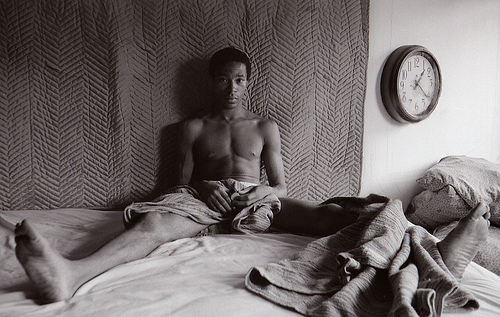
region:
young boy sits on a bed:
[144, 29, 295, 178]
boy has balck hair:
[146, 27, 308, 215]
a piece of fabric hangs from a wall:
[10, 3, 362, 191]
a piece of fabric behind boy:
[7, 4, 358, 201]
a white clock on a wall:
[380, 39, 450, 133]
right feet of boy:
[8, 211, 90, 316]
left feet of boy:
[431, 191, 496, 290]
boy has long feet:
[10, 36, 498, 316]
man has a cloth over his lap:
[134, 36, 316, 245]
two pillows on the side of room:
[380, 142, 495, 233]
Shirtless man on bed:
[30, 36, 310, 286]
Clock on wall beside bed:
[378, 35, 441, 127]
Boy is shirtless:
[163, 50, 292, 190]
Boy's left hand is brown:
[241, 181, 271, 206]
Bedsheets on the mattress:
[129, 245, 341, 312]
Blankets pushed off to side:
[382, 153, 497, 280]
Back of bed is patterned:
[11, 13, 370, 193]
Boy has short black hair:
[206, 42, 260, 77]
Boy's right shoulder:
[168, 112, 202, 142]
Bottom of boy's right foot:
[13, 222, 83, 296]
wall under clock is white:
[370, 10, 490, 165]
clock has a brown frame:
[372, 37, 443, 129]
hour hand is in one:
[406, 50, 431, 87]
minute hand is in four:
[412, 78, 433, 103]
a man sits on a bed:
[1, 42, 408, 312]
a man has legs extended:
[3, 33, 411, 313]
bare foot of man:
[8, 212, 89, 313]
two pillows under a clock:
[402, 145, 497, 227]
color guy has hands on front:
[148, 44, 301, 234]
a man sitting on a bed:
[14, 42, 491, 314]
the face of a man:
[207, 47, 254, 111]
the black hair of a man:
[208, 48, 248, 72]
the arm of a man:
[260, 115, 290, 201]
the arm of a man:
[178, 118, 206, 192]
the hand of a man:
[237, 183, 266, 205]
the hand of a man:
[206, 181, 233, 216]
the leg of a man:
[77, 194, 210, 285]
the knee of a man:
[141, 208, 166, 230]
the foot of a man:
[18, 221, 74, 304]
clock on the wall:
[378, 42, 443, 125]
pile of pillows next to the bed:
[407, 146, 497, 279]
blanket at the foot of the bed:
[242, 196, 481, 316]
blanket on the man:
[124, 179, 285, 232]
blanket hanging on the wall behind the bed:
[2, 11, 370, 205]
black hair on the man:
[202, 46, 255, 80]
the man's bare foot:
[8, 217, 87, 312]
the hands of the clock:
[409, 68, 435, 101]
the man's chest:
[189, 115, 264, 181]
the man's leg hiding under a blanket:
[276, 196, 491, 284]